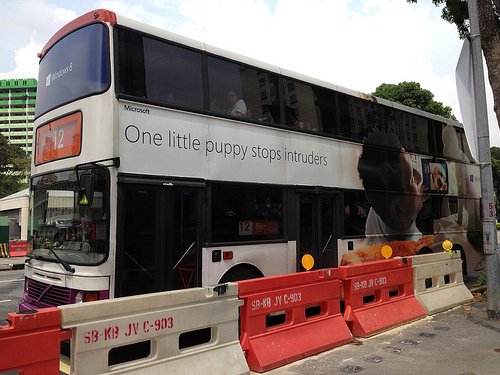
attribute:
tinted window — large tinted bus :
[345, 192, 395, 240]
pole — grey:
[466, 1, 499, 320]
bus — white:
[38, 22, 498, 326]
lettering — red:
[80, 310, 188, 350]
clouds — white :
[287, 4, 356, 49]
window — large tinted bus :
[400, 118, 441, 157]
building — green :
[2, 77, 32, 162]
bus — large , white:
[15, 6, 478, 321]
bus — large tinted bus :
[28, 2, 436, 317]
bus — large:
[37, 12, 338, 274]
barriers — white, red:
[0, 247, 475, 373]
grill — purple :
[21, 282, 71, 307]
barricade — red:
[217, 257, 373, 373]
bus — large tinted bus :
[180, 170, 307, 230]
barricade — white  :
[167, 286, 250, 334]